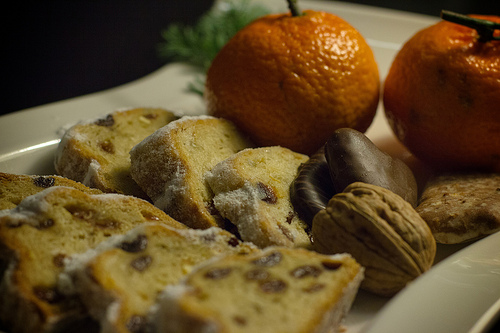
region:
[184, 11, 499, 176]
two oranges on a plate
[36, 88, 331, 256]
a row of bread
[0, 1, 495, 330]
food on a plate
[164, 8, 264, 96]
green leaves on the corner of the plate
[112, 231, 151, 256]
dark spot on the bread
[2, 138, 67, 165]
light shining on the plate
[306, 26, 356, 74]
light shining on the orange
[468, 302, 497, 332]
edge of the plate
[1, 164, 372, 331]
four pieces of bread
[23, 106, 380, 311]
sliced bread on plate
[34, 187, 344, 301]
brown raisins in bread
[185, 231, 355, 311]
bread has orange crust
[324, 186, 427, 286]
large walnuts on plate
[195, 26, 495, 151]
two oranges on plate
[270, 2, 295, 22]
small stem on orange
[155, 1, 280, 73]
green garnish on plate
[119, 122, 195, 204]
bread is dusted with sugar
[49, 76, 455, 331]
plate is shiny and white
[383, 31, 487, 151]
shiny rind on orange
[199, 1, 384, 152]
An orange on a plate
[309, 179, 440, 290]
a walnut on a plate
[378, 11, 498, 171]
an orange on a plate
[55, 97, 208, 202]
a piece of bread on a plate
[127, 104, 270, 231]
a piece of bread on a plate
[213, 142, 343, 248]
a piece of bread on a plate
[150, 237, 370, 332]
a piece of bread on a plate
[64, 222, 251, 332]
a piece of bread on a plate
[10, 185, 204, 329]
a piece of bread on a plate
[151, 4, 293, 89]
a piece of parsley on a plate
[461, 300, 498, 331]
edge of the plate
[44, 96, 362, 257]
a stack of bread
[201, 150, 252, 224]
white powder on the crust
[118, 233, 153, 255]
dark spot on the bread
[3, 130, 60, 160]
light shining on the plate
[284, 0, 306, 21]
stem sticking out of the orange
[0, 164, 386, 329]
four pieces of bread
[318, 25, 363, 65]
light shining on the orange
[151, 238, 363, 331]
slice of banana nut bread on a platter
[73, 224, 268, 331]
slice of banana nut bread on a platter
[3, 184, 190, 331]
slice of banana nut bread on a platter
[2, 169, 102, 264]
slice of banana nut bread on a platter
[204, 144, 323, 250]
slice of banana nut bread on a platter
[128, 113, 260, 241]
slice of banana nut bread on a platter